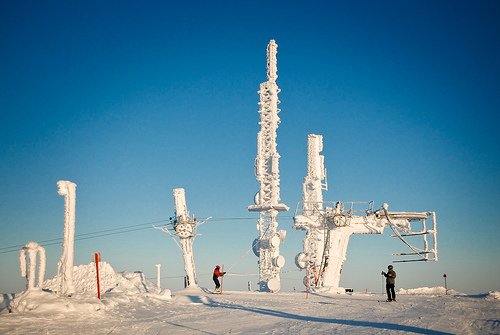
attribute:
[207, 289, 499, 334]
snow — white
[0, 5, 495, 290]
sky — blue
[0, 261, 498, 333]
snow — white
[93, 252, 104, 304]
pole — orange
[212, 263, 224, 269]
hat — red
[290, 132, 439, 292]
equipment — frozen, utility, pole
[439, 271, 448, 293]
pole — small, sign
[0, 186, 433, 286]
chair — ski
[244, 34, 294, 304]
snowy structure — tall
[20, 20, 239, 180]
patch — large